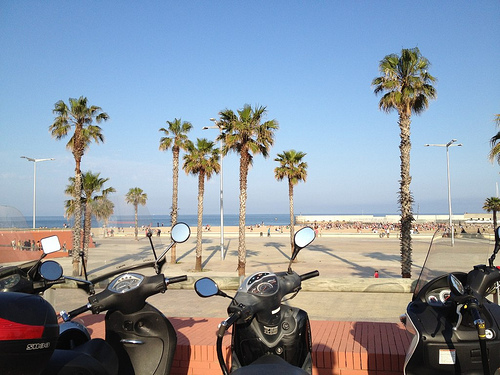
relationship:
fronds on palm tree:
[216, 103, 279, 166] [215, 104, 279, 278]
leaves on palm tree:
[148, 91, 199, 267] [158, 118, 194, 265]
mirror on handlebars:
[152, 220, 187, 274] [58, 257, 186, 321]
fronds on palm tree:
[220, 106, 270, 181] [48, 97, 110, 278]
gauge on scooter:
[248, 268, 283, 299] [37, 218, 192, 373]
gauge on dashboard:
[248, 268, 283, 299] [232, 270, 294, 305]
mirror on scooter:
[38, 233, 60, 256] [0, 232, 92, 305]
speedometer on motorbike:
[251, 278, 279, 298] [193, 226, 319, 375]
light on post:
[17, 156, 25, 163] [32, 161, 37, 231]